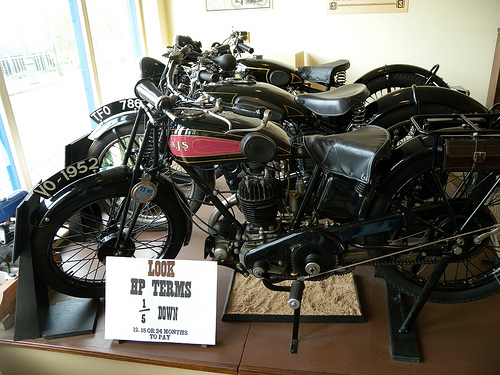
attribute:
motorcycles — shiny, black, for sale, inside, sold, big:
[35, 34, 499, 302]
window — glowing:
[3, 4, 108, 184]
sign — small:
[105, 255, 216, 345]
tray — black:
[222, 271, 364, 322]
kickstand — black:
[291, 301, 301, 352]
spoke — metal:
[81, 209, 171, 238]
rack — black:
[411, 113, 498, 141]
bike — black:
[34, 45, 499, 305]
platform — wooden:
[4, 164, 498, 373]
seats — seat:
[301, 123, 392, 187]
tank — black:
[242, 133, 278, 167]